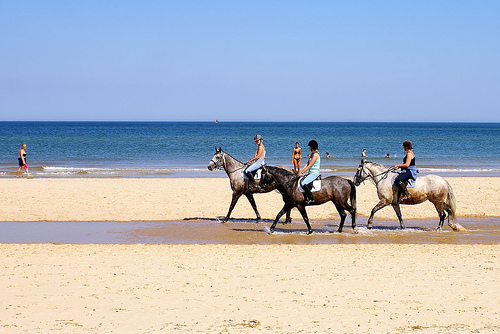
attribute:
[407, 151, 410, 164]
top —  black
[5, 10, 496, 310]
scene — outdoors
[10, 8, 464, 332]
scene — outdoors